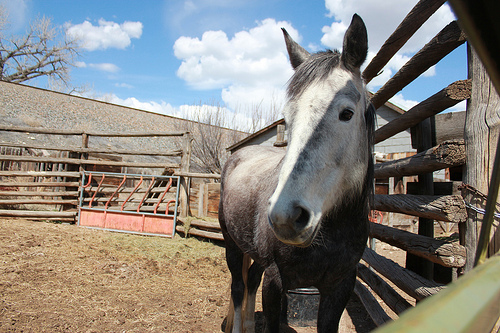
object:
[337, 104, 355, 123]
eye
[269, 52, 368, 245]
face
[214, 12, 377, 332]
horse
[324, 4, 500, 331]
fence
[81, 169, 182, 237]
gate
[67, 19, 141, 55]
clouds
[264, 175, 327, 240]
nose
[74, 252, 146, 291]
hay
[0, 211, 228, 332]
ground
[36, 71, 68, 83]
branches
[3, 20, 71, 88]
tree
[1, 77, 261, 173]
roof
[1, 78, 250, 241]
barn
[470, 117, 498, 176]
wood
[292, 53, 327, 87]
mane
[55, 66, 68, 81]
leaves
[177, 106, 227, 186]
trees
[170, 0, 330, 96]
sky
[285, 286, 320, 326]
bucket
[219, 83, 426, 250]
house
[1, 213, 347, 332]
grass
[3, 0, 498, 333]
pen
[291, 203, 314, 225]
nostril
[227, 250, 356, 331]
legs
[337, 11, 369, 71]
ears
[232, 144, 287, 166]
back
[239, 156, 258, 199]
fur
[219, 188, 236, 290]
tail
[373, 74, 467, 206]
back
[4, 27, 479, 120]
distance